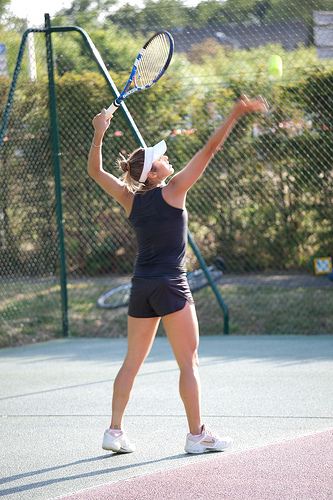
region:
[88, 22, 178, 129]
blue and white tennis racquet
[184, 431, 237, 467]
pink and white tennis shoe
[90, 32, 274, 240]
female swinging racquet at tennis ball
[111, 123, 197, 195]
woman wearing white visor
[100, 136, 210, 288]
woman wearing dark shirt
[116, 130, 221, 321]
woman wearing dark shorts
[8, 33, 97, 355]
green fencing and poles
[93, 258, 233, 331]
bicycle laying on the ground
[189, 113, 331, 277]
trees behind the fence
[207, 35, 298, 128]
tennis ball thrown in air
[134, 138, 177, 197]
Person wearing white visor.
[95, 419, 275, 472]
Person wearing white and pink shoes.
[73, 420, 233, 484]
Person playing tennis.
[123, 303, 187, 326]
Person wearing black shorts.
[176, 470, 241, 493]
Tennis court is brownish gray in color.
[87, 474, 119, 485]
White line on tennis court.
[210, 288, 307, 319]
Court inside of fence.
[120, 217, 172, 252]
Woman wearing black shirt.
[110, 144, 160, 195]
Woman has hair pulled back in bun.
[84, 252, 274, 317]
Bike on the ground outside of the fence.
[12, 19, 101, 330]
A large fence.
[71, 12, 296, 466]
The woman is serving the ball.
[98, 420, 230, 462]
Pink and white sneakers.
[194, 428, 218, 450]
The manufacturer's logo.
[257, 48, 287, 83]
A tennis ball.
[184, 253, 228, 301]
A bicycle is on the ground.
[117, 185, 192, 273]
The woman is wearing a black tank top.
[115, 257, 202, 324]
The woman is wearing black shorts.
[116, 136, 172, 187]
A white visor.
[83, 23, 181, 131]
A tennis racket is in the woman's left hand.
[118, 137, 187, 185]
She is wearing a white visor.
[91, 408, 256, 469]
She has white shoes on.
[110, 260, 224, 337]
She has black shorts on.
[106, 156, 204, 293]
She has a black shirt on.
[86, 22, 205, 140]
Her racket is blue and black.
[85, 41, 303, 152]
She is swinging the racket.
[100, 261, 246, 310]
The bike is on the ground.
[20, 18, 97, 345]
The pole is green.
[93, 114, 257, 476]
She is playing tennis.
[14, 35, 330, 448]
The sun is shining.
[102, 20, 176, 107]
woman holding tennis racquet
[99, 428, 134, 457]
woman wearing pink and white shoe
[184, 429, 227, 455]
woman wearing pink and white shoe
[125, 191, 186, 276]
woman wearing black top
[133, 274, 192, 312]
woman wearing black shorts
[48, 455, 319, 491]
gray and pink tennis court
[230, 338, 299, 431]
gray tennis court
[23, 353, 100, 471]
gray tennis court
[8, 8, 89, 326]
green metal fence around tennis court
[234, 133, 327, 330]
green metal fence around tennis court